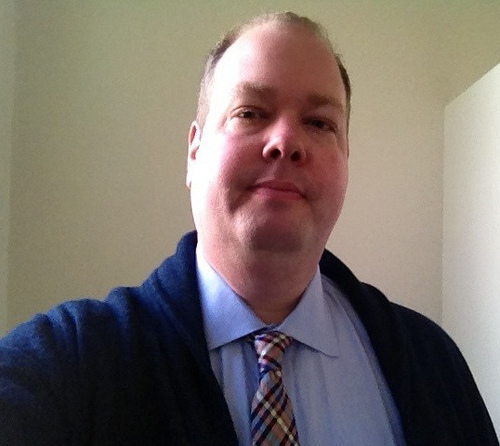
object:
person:
[0, 7, 500, 446]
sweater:
[0, 228, 498, 446]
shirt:
[184, 245, 410, 445]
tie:
[247, 329, 304, 444]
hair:
[187, 9, 367, 164]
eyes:
[226, 104, 270, 123]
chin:
[225, 203, 317, 258]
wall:
[2, 0, 500, 446]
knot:
[253, 334, 291, 382]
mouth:
[247, 175, 305, 206]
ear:
[185, 122, 204, 192]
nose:
[260, 102, 309, 165]